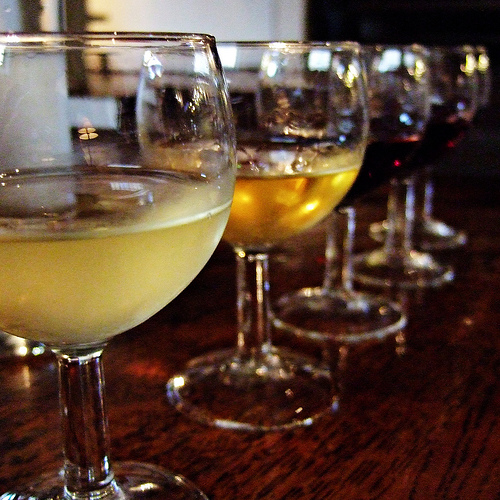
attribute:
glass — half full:
[2, 30, 238, 498]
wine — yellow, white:
[0, 167, 236, 347]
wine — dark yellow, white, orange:
[150, 146, 368, 251]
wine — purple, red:
[269, 134, 420, 213]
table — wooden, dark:
[1, 131, 499, 499]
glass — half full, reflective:
[136, 40, 370, 439]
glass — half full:
[253, 43, 436, 342]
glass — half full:
[341, 43, 481, 288]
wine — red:
[403, 118, 474, 178]